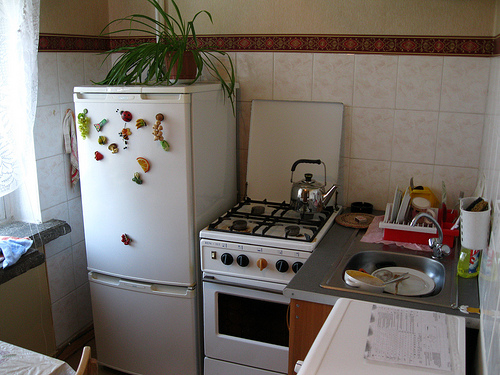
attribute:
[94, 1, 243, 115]
plant — potted, green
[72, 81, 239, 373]
refrigerator — white, present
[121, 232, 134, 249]
magnet — colorful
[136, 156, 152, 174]
magnet — orange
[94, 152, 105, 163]
magnet — colorful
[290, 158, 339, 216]
teakettle — silver, shiny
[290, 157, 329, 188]
handle — black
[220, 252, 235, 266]
knob — black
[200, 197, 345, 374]
stove — white, gas, present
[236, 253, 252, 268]
knob — black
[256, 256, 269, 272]
knob — brown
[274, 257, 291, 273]
knob — black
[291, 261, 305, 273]
knob — black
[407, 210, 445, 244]
faucet — silver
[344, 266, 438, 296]
dishes — dirty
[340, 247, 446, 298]
sink — steel, present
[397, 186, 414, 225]
dish — clean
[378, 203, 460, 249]
holder — red, white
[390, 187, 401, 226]
dish — clean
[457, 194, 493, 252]
holder — white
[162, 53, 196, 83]
pot — terra cotta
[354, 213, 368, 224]
matches — present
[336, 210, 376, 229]
mat — wicker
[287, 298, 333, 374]
cabinet — wooden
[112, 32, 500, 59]
border — floral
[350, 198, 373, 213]
ashtray — black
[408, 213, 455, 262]
tap — present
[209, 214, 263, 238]
burner — gas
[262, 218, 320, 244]
burner — gas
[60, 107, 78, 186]
towel — hanging